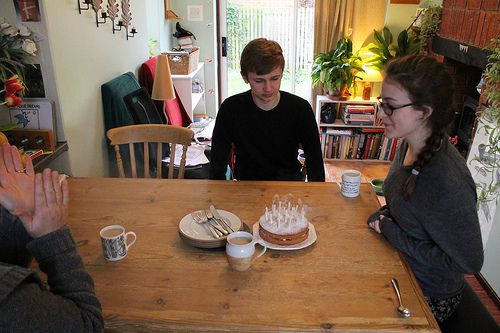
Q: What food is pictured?
A: A cake.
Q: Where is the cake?
A: On a plate.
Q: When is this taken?
A: Daytime.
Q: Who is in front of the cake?
A: A woman.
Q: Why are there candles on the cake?
A: It is a birthday.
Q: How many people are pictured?
A: Three.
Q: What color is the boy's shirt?
A: Black.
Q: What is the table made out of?
A: Wood.